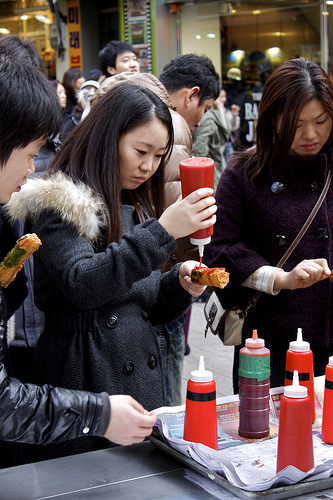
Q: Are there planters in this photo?
A: No, there are no planters.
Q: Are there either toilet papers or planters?
A: No, there are no planters or toilet papers.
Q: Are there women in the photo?
A: Yes, there is a woman.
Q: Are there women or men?
A: Yes, there is a woman.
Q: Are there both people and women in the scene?
A: Yes, there are both a woman and people.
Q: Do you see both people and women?
A: Yes, there are both a woman and people.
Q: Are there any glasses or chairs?
A: No, there are no glasses or chairs.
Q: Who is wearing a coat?
A: The woman is wearing a coat.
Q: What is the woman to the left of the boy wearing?
A: The woman is wearing a coat.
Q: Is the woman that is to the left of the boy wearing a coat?
A: Yes, the woman is wearing a coat.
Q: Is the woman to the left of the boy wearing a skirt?
A: No, the woman is wearing a coat.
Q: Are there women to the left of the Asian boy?
A: Yes, there is a woman to the left of the boy.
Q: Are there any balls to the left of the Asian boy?
A: No, there is a woman to the left of the boy.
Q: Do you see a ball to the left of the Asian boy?
A: No, there is a woman to the left of the boy.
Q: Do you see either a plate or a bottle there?
A: Yes, there is a bottle.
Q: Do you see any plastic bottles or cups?
A: Yes, there is a plastic bottle.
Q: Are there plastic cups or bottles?
A: Yes, there is a plastic bottle.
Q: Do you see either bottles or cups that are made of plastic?
A: Yes, the bottle is made of plastic.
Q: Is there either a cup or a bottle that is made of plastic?
A: Yes, the bottle is made of plastic.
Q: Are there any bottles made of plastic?
A: Yes, there is a bottle that is made of plastic.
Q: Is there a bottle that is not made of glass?
A: Yes, there is a bottle that is made of plastic.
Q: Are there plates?
A: No, there are no plates.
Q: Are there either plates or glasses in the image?
A: No, there are no plates or glasses.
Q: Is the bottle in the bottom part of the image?
A: Yes, the bottle is in the bottom of the image.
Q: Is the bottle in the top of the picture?
A: No, the bottle is in the bottom of the image.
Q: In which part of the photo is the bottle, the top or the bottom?
A: The bottle is in the bottom of the image.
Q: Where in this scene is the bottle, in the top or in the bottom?
A: The bottle is in the bottom of the image.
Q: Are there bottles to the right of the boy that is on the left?
A: Yes, there is a bottle to the right of the boy.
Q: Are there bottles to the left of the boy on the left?
A: No, the bottle is to the right of the boy.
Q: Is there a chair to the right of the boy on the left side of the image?
A: No, there is a bottle to the right of the boy.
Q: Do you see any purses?
A: Yes, there is a purse.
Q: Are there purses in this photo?
A: Yes, there is a purse.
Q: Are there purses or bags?
A: Yes, there is a purse.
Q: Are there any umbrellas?
A: No, there are no umbrellas.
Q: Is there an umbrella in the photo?
A: No, there are no umbrellas.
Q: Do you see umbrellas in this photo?
A: No, there are no umbrellas.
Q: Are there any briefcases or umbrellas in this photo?
A: No, there are no umbrellas or briefcases.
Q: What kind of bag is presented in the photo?
A: The bag is a purse.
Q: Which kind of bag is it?
A: The bag is a purse.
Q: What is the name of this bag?
A: This is a purse.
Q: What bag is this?
A: This is a purse.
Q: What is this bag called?
A: This is a purse.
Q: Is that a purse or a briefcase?
A: That is a purse.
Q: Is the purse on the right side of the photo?
A: Yes, the purse is on the right of the image.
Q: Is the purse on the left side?
A: No, the purse is on the right of the image.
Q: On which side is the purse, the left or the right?
A: The purse is on the right of the image.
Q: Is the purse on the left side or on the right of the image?
A: The purse is on the right of the image.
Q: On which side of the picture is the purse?
A: The purse is on the right of the image.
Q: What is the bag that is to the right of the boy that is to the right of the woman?
A: The bag is a purse.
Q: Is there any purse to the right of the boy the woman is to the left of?
A: Yes, there is a purse to the right of the boy.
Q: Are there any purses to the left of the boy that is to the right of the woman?
A: No, the purse is to the right of the boy.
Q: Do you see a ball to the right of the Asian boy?
A: No, there is a purse to the right of the boy.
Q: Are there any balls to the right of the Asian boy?
A: No, there is a purse to the right of the boy.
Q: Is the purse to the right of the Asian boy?
A: Yes, the purse is to the right of the boy.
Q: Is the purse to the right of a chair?
A: No, the purse is to the right of the boy.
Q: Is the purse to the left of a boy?
A: No, the purse is to the right of a boy.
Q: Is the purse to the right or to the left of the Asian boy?
A: The purse is to the right of the boy.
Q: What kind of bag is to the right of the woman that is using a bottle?
A: The bag is a purse.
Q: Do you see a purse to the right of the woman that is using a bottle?
A: Yes, there is a purse to the right of the woman.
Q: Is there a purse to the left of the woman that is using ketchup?
A: No, the purse is to the right of the woman.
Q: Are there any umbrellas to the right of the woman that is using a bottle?
A: No, there is a purse to the right of the woman.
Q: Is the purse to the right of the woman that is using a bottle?
A: Yes, the purse is to the right of the woman.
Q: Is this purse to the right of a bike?
A: No, the purse is to the right of the woman.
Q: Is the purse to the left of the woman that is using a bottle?
A: No, the purse is to the right of the woman.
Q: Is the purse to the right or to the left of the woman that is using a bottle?
A: The purse is to the right of the woman.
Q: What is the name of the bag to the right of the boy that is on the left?
A: The bag is a purse.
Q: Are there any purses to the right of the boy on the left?
A: Yes, there is a purse to the right of the boy.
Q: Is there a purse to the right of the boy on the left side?
A: Yes, there is a purse to the right of the boy.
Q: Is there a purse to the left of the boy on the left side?
A: No, the purse is to the right of the boy.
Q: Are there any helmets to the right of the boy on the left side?
A: No, there is a purse to the right of the boy.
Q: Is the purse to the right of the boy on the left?
A: Yes, the purse is to the right of the boy.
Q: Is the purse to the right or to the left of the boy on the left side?
A: The purse is to the right of the boy.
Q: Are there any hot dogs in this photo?
A: Yes, there is a hot dog.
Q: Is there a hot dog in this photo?
A: Yes, there is a hot dog.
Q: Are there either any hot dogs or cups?
A: Yes, there is a hot dog.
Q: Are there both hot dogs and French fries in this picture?
A: No, there is a hot dog but no fries.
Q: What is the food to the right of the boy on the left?
A: The food is a hot dog.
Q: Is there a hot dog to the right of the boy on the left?
A: Yes, there is a hot dog to the right of the boy.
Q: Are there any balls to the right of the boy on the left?
A: No, there is a hot dog to the right of the boy.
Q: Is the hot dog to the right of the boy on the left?
A: Yes, the hot dog is to the right of the boy.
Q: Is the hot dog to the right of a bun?
A: No, the hot dog is to the right of the boy.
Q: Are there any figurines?
A: No, there are no figurines.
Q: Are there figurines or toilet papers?
A: No, there are no figurines or toilet papers.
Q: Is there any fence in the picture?
A: No, there are no fences.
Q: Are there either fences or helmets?
A: No, there are no fences or helmets.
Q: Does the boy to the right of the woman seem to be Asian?
A: Yes, the boy is asian.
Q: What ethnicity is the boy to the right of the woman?
A: The boy is asian.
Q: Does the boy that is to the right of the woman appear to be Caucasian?
A: No, the boy is asian.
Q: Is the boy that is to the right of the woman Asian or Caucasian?
A: The boy is asian.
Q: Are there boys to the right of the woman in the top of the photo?
A: Yes, there is a boy to the right of the woman.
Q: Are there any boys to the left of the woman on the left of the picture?
A: No, the boy is to the right of the woman.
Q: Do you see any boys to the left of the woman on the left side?
A: No, the boy is to the right of the woman.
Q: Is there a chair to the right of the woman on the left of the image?
A: No, there is a boy to the right of the woman.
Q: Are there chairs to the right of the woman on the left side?
A: No, there is a boy to the right of the woman.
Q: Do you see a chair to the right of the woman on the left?
A: No, there is a boy to the right of the woman.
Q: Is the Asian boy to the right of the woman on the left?
A: Yes, the boy is to the right of the woman.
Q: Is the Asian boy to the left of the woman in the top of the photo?
A: No, the boy is to the right of the woman.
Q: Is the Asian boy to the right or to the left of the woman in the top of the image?
A: The boy is to the right of the woman.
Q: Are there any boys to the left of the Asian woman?
A: Yes, there is a boy to the left of the woman.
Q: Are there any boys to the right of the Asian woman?
A: No, the boy is to the left of the woman.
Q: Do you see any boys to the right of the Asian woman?
A: No, the boy is to the left of the woman.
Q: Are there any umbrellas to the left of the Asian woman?
A: No, there is a boy to the left of the woman.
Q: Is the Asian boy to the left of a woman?
A: Yes, the boy is to the left of a woman.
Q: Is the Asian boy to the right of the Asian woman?
A: No, the boy is to the left of the woman.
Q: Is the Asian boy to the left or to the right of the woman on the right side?
A: The boy is to the left of the woman.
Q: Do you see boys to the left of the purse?
A: Yes, there is a boy to the left of the purse.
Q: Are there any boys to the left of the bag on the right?
A: Yes, there is a boy to the left of the purse.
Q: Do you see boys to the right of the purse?
A: No, the boy is to the left of the purse.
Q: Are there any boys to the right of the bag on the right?
A: No, the boy is to the left of the purse.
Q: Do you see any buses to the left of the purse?
A: No, there is a boy to the left of the purse.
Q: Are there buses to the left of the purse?
A: No, there is a boy to the left of the purse.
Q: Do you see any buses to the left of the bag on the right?
A: No, there is a boy to the left of the purse.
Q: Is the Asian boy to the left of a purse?
A: Yes, the boy is to the left of a purse.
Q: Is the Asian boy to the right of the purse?
A: No, the boy is to the left of the purse.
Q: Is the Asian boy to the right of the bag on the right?
A: No, the boy is to the left of the purse.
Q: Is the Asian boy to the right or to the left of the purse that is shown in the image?
A: The boy is to the left of the purse.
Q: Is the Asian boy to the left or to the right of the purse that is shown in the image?
A: The boy is to the left of the purse.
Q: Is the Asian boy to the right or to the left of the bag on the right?
A: The boy is to the left of the purse.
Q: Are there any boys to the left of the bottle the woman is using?
A: Yes, there is a boy to the left of the bottle.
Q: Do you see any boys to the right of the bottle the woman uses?
A: No, the boy is to the left of the bottle.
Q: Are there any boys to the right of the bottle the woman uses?
A: No, the boy is to the left of the bottle.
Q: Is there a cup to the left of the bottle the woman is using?
A: No, there is a boy to the left of the bottle.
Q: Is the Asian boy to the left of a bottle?
A: Yes, the boy is to the left of a bottle.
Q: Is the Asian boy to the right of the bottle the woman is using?
A: No, the boy is to the left of the bottle.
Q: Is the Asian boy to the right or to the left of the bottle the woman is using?
A: The boy is to the left of the bottle.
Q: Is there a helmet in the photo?
A: No, there are no helmets.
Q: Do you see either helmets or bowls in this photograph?
A: No, there are no helmets or bowls.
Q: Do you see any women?
A: Yes, there is a woman.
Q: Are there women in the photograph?
A: Yes, there is a woman.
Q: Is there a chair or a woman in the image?
A: Yes, there is a woman.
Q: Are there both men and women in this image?
A: Yes, there are both a woman and a man.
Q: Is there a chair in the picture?
A: No, there are no chairs.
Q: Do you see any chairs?
A: No, there are no chairs.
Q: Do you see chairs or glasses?
A: No, there are no chairs or glasses.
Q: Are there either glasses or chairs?
A: No, there are no chairs or glasses.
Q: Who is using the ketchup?
A: The woman is using the ketchup.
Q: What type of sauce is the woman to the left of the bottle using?
A: The woman is using ketchup.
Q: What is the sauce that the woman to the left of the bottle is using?
A: The sauce is ketchup.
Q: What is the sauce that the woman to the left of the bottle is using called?
A: The sauce is ketchup.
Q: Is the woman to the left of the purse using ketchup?
A: Yes, the woman is using ketchup.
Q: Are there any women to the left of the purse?
A: Yes, there is a woman to the left of the purse.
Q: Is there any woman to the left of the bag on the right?
A: Yes, there is a woman to the left of the purse.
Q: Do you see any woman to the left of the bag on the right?
A: Yes, there is a woman to the left of the purse.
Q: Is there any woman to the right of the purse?
A: No, the woman is to the left of the purse.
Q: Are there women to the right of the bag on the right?
A: No, the woman is to the left of the purse.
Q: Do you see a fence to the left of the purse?
A: No, there is a woman to the left of the purse.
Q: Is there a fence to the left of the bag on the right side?
A: No, there is a woman to the left of the purse.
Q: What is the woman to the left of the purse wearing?
A: The woman is wearing a coat.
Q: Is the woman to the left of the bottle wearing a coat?
A: Yes, the woman is wearing a coat.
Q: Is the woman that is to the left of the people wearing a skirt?
A: No, the woman is wearing a coat.